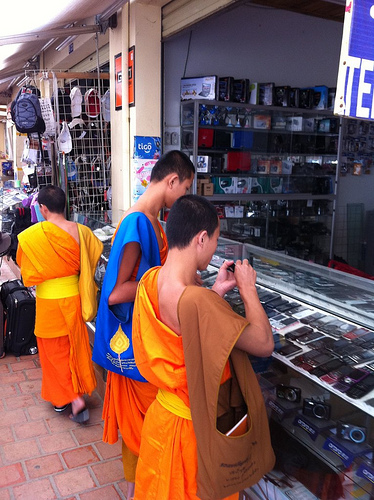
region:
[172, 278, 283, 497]
THE MAN IS CARRYING A BROWN BAG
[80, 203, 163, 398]
THE MAN IS CARRYING A BLUE BAG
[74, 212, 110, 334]
THE MAN IS CARRYING A YELLOW BAG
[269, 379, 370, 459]
THE CAMERAS ARE IN THE CASE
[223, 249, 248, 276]
THE MAN IS HOLDING A CAMERA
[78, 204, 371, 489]
THE CASE IS LONG AND GLASS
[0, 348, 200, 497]
THE SIDEWALK IS BRICK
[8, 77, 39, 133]
THE BACKPACK IS GREY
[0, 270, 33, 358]
THE SUITCASES ARE BLACK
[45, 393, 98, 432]
THE MAN IS WEARING SANDALS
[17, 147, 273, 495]
A trio of monks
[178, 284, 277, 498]
A brown shoulder bag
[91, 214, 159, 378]
A blue shoulder bag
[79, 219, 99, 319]
A yellow shoulder bag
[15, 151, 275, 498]
Monks in orange robes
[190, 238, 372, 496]
A case full of merchandise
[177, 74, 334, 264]
A shelf lined with products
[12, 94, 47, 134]
A gray backpack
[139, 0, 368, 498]
A street vendors kiosk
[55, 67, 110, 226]
A metal rack filled with merchandise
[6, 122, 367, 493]
young monks shopping in market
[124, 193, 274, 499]
Young man with brown bag over shoulder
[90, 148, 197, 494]
Young man wearing blue bag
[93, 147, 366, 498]
young men looking at cell phones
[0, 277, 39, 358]
Black suitcase with wheels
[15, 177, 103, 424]
Person wearing yellow and orange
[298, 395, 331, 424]
black camera inside glass case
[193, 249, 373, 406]
Cell phones inside glass case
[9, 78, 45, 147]
Backpack hanging on white rack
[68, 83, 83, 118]
white cap on white rack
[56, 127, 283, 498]
two people looking at a phone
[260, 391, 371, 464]
cameras on display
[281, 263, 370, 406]
mobile phones are on display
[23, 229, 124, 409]
they are wearing orange sarees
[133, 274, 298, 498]
the man has a brown bag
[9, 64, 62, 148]
a bag is on display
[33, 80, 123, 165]
caps are hanged on a wire mesh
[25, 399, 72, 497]
the floor is brown in colour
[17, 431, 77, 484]
it has rectangular slabs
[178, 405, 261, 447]
a book is in the bag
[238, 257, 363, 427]
in shop mobile and cameras kept for sale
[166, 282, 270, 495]
a person holding shoulder bag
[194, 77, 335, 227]
some elcetronic accessories in the shop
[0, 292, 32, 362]
black color brief case kept in the side walk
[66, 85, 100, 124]
hat for sale hanging in the steel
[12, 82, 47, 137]
backbag kept for sale in front of the shop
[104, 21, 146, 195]
cream color coatings in the wall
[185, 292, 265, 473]
brown color shoulder bag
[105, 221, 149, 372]
a person holding blue color shoulder bag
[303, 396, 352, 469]
camera kept for sale with price tag